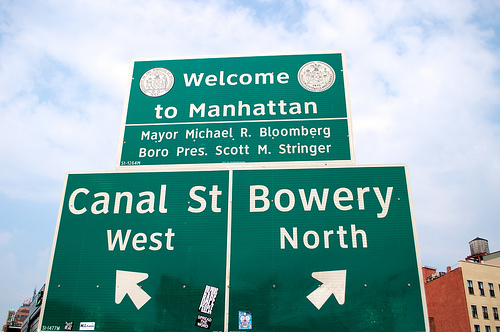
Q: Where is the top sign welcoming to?
A: Manhattan.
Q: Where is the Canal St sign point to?
A: West.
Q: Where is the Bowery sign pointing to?
A: North.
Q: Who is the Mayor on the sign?
A: Michael R. Bloomberg.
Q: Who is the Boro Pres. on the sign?
A: Scott M. Stringer.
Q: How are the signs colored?
A: Green.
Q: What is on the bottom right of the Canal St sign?
A: Black sticker.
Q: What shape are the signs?
A: Square.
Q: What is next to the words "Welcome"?
A: Seals.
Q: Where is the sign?
A: Manhattan.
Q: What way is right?
A: Bowery north.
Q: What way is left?
A: Canal st west.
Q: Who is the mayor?
A: Michael r bloomberg.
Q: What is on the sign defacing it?
A: Stickers.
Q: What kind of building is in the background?
A: Brick.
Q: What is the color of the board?
A: Green.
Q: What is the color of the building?
A: Red.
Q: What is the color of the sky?
A: Blue.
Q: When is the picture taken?
A: Daytime.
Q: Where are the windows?
A: In the building wall.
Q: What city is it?
A: Manhattan.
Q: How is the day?
A: Sunny.